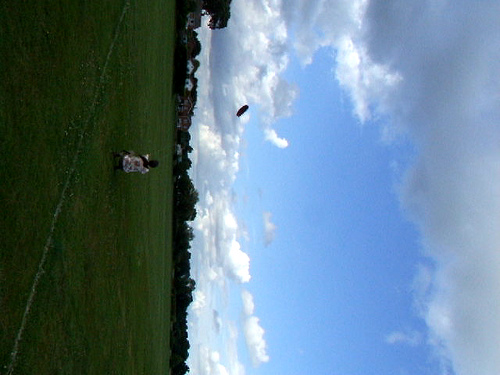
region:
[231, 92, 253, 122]
black object in sky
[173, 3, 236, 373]
line of trees and foliage lining green field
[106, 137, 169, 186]
person in grass field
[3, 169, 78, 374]
white line drawn on green field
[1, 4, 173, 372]
large field of green grass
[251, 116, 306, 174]
white cloud in blue sky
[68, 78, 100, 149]
white flowers in green grass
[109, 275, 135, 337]
pale patch in gree grass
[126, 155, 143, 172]
blemisg on back of person's shirt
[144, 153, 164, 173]
black hair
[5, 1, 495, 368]
the picture is sideways.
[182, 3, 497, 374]
the sky is blue.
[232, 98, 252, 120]
kite in the sky.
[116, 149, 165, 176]
person sitting on the ground.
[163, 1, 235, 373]
trees in the distance.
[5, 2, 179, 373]
the grass is green.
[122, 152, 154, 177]
person's shirt is white.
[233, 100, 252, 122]
the kite is black.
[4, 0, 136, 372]
white line in the grass.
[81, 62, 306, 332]
this is at a park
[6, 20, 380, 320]
the photo is sideways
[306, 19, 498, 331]
the sky is partly cloudy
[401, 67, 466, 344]
the clouds are gray and white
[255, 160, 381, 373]
the sky is light baby blue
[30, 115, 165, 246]
this person is flying a kite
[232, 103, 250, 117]
a kite in the air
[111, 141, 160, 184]
a person crouching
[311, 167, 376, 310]
blue skies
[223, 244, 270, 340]
white clouds in the sky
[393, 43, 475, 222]
dark clouds in the sky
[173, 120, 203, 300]
trees in the distant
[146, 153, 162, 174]
the head of a person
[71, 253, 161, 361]
green grass on the ground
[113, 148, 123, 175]
the legs of a person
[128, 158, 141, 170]
the back of a person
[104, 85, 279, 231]
A person flying a kite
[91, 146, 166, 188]
Person in black and white shirt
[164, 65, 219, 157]
Red houses in the background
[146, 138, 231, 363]
A line of trees in the background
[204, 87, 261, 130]
A black kite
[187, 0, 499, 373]
clouds surrounding blue sky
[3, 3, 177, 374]
large flat green field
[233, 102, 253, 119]
kite in the sky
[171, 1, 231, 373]
line of trees along field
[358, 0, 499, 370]
dark grey clouds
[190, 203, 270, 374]
fluffy white clouds in blue sky